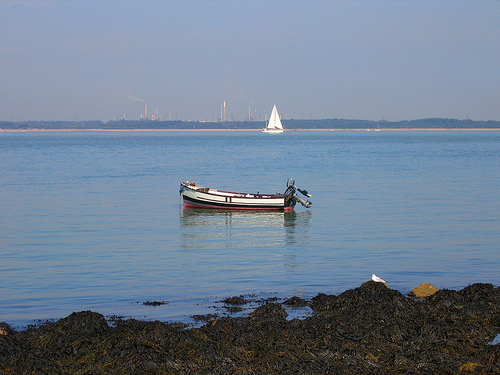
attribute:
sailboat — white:
[263, 102, 287, 137]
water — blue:
[3, 129, 499, 317]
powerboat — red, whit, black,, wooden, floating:
[177, 181, 312, 213]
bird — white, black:
[367, 270, 389, 288]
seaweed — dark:
[2, 287, 499, 373]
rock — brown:
[410, 282, 436, 299]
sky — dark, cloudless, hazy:
[1, 2, 500, 123]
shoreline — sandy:
[2, 115, 498, 133]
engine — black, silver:
[286, 188, 311, 215]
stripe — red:
[183, 203, 289, 210]